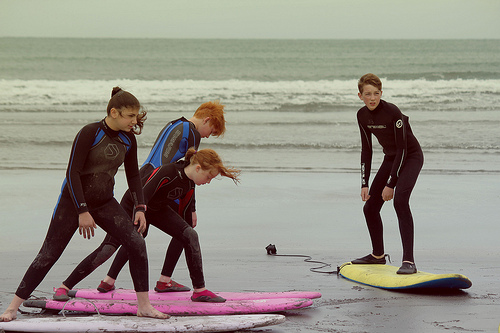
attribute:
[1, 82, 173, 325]
girl — learning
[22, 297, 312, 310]
surfboard — orange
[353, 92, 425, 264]
swimsuit — black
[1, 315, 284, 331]
surfboard — white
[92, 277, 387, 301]
surf board — white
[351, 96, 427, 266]
wet suit — black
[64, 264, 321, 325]
surfboards — pink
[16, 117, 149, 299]
wetsuit — black, blue, wet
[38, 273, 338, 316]
boards — pink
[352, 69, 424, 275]
kid — four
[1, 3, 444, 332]
kids — learning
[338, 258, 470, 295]
surfboard — yellow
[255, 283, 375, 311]
surfboard — white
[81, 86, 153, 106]
hair — black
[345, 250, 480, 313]
board — for surf board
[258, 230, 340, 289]
leash — for safety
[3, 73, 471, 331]
kids — doing lessons